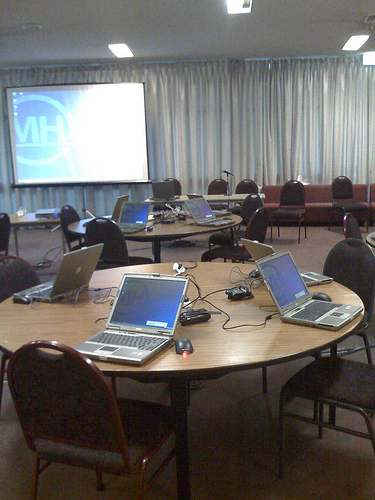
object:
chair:
[6, 337, 177, 499]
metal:
[108, 389, 121, 427]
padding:
[42, 368, 78, 442]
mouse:
[175, 334, 193, 356]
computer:
[70, 271, 193, 367]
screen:
[0, 81, 151, 187]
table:
[0, 257, 367, 372]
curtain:
[165, 86, 204, 170]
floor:
[210, 411, 271, 479]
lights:
[108, 40, 134, 59]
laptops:
[10, 243, 103, 301]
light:
[182, 350, 188, 357]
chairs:
[269, 180, 310, 243]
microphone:
[34, 206, 67, 221]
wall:
[155, 74, 225, 169]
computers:
[183, 195, 235, 227]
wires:
[205, 286, 226, 298]